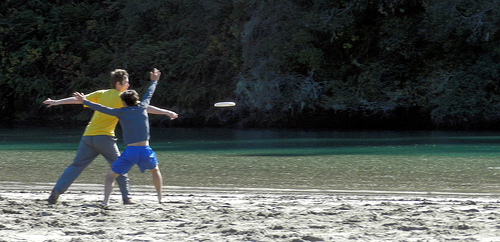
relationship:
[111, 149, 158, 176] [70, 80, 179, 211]
shorts on boy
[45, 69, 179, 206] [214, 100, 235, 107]
boy playing with a frisbee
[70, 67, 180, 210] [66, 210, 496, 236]
boy playing on beach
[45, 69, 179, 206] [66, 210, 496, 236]
boy playing on beach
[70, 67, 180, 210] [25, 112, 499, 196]
boy playing next to water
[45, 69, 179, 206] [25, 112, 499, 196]
boy playing next to water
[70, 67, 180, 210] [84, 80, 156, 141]
boy in blue shirt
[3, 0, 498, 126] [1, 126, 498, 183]
trees behind water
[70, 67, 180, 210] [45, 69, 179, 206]
boy blocking boy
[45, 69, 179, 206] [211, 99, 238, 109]
boy playing frisbee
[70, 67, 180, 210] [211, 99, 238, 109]
boy playing frisbee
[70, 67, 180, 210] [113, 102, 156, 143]
boy wearing shirt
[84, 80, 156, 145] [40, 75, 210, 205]
blue shirt on boy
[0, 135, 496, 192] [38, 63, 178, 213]
water behind men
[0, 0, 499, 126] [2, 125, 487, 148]
trees are along edge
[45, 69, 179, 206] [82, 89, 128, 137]
boy in shirt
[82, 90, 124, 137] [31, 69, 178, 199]
shirt on man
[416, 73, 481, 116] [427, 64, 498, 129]
leaves are on tree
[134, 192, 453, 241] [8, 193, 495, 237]
sand on beach